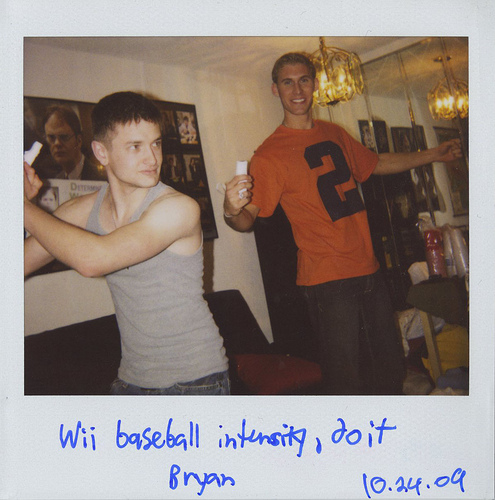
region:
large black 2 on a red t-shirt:
[246, 119, 379, 285]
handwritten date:
[348, 464, 481, 498]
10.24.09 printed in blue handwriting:
[342, 462, 494, 498]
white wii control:
[236, 162, 248, 196]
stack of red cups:
[421, 222, 444, 278]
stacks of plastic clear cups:
[440, 220, 469, 277]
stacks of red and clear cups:
[422, 223, 467, 278]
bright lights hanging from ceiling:
[425, 44, 465, 125]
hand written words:
[56, 415, 480, 498]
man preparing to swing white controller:
[23, 87, 217, 395]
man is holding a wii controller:
[206, 157, 270, 229]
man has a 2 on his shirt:
[247, 125, 401, 281]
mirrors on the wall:
[355, 48, 494, 217]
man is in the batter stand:
[32, 126, 210, 334]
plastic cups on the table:
[425, 218, 490, 291]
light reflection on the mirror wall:
[414, 41, 467, 147]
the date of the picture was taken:
[346, 461, 471, 498]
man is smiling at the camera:
[248, 42, 361, 150]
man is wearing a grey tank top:
[70, 166, 260, 378]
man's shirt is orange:
[259, 120, 414, 310]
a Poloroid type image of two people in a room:
[2, 2, 493, 499]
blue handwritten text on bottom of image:
[44, 407, 397, 497]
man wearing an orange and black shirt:
[247, 50, 388, 284]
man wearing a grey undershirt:
[72, 92, 237, 390]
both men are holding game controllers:
[24, 62, 328, 272]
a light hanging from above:
[297, 36, 379, 110]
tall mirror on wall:
[317, 36, 467, 322]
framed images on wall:
[21, 92, 228, 279]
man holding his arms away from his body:
[209, 44, 465, 245]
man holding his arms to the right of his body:
[22, 82, 206, 284]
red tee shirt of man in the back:
[249, 117, 370, 285]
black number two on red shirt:
[303, 140, 371, 218]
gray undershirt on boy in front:
[84, 179, 226, 387]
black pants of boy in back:
[294, 282, 395, 389]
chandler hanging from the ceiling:
[309, 36, 364, 102]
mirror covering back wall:
[338, 39, 465, 261]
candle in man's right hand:
[233, 157, 248, 211]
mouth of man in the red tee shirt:
[285, 91, 308, 106]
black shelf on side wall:
[24, 93, 214, 275]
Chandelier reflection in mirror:
[417, 44, 471, 118]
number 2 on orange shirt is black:
[303, 137, 366, 219]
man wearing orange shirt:
[216, 48, 465, 392]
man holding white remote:
[218, 48, 461, 394]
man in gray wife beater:
[23, 91, 232, 395]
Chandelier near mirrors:
[295, 36, 367, 107]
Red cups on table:
[419, 217, 446, 275]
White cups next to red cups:
[449, 226, 467, 277]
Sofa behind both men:
[25, 281, 269, 395]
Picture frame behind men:
[139, 92, 218, 239]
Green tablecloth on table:
[403, 275, 467, 325]